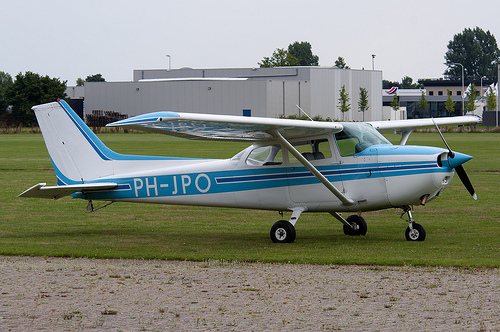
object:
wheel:
[270, 220, 297, 243]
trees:
[336, 84, 351, 121]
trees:
[358, 86, 370, 121]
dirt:
[0, 256, 500, 332]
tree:
[257, 41, 321, 68]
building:
[418, 80, 494, 96]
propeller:
[432, 117, 478, 200]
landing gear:
[400, 206, 426, 242]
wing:
[17, 183, 117, 200]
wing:
[106, 111, 484, 143]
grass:
[0, 125, 500, 269]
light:
[443, 62, 464, 115]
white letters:
[134, 173, 211, 197]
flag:
[385, 87, 398, 95]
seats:
[301, 152, 325, 160]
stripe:
[57, 101, 112, 160]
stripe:
[107, 117, 158, 126]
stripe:
[215, 164, 438, 183]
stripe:
[56, 176, 130, 192]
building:
[63, 67, 381, 122]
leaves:
[441, 26, 500, 81]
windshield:
[334, 123, 391, 156]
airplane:
[16, 99, 483, 243]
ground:
[0, 125, 500, 332]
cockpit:
[246, 124, 394, 167]